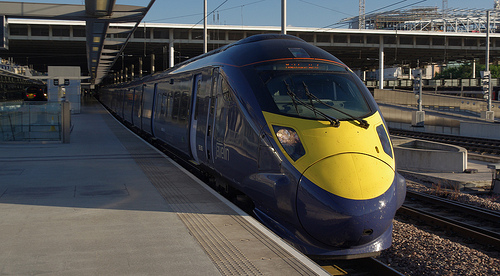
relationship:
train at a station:
[106, 33, 409, 262] [1, 2, 499, 274]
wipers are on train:
[287, 85, 369, 129] [106, 33, 409, 262]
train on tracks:
[106, 33, 409, 262] [383, 126, 497, 274]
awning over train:
[79, 0, 148, 96] [106, 33, 409, 262]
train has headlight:
[106, 33, 409, 262] [279, 126, 306, 159]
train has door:
[106, 33, 409, 262] [188, 71, 201, 166]